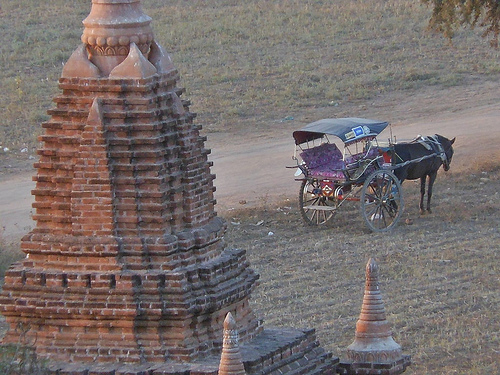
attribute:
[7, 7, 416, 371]
statue — large, stone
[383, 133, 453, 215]
horse — black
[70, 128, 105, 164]
brick — red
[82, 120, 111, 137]
brick — red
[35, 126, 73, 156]
brick — red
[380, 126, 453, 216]
horse — one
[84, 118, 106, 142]
brick — one